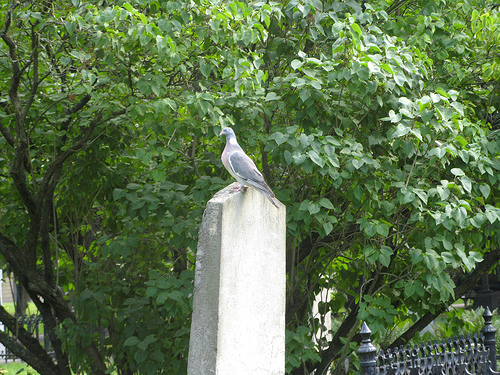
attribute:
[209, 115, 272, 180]
bird — tiny, sitting, black, small, gray, outdoors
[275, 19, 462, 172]
trees — green, bushy, lush, alive, healthy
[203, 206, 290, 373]
stone — gray, old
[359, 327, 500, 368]
fence — black